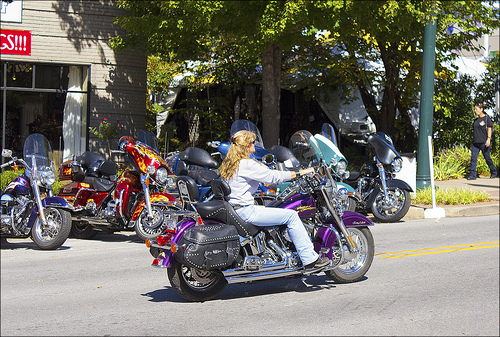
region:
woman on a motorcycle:
[139, 128, 386, 287]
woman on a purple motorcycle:
[143, 130, 387, 292]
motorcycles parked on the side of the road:
[0, 115, 227, 240]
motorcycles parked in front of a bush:
[0, 107, 175, 252]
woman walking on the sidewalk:
[452, 77, 497, 202]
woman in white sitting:
[218, 123, 329, 278]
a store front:
[0, 22, 130, 154]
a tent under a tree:
[157, 26, 402, 132]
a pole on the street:
[412, 130, 457, 221]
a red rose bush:
[86, 109, 123, 160]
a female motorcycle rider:
[8, 9, 460, 293]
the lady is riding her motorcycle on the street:
[143, 115, 433, 312]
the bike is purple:
[145, 194, 382, 296]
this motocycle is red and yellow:
[54, 141, 182, 218]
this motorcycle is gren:
[0, 143, 98, 260]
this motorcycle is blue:
[178, 127, 300, 205]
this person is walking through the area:
[453, 92, 497, 186]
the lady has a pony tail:
[213, 124, 263, 179]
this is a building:
[5, 2, 97, 151]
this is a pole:
[400, 18, 442, 202]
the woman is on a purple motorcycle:
[146, 128, 385, 296]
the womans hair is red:
[210, 123, 265, 185]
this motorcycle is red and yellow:
[54, 132, 190, 248]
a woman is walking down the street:
[458, 99, 499, 181]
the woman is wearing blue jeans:
[468, 135, 497, 187]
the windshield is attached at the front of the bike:
[18, 130, 50, 168]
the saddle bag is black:
[186, 224, 244, 270]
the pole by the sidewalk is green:
[416, 14, 438, 193]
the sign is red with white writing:
[2, 31, 31, 56]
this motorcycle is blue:
[2, 149, 74, 250]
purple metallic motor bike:
[163, 191, 372, 288]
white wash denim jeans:
[234, 204, 319, 267]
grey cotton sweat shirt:
[226, 158, 292, 205]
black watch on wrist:
[296, 169, 301, 178]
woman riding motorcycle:
[225, 131, 331, 276]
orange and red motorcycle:
[58, 142, 178, 245]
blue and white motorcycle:
[280, 129, 354, 205]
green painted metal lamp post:
[416, 17, 435, 190]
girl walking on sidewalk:
[469, 103, 495, 175]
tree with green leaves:
[111, 1, 457, 141]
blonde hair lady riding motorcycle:
[219, 128, 330, 270]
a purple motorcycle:
[150, 164, 376, 266]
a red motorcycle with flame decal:
[62, 144, 178, 216]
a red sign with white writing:
[1, 30, 31, 52]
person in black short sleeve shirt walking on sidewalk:
[466, 99, 496, 177]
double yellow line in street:
[372, 238, 497, 262]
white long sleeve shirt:
[223, 158, 290, 203]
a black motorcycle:
[328, 130, 410, 220]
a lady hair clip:
[229, 135, 236, 144]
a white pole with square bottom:
[419, 138, 442, 215]